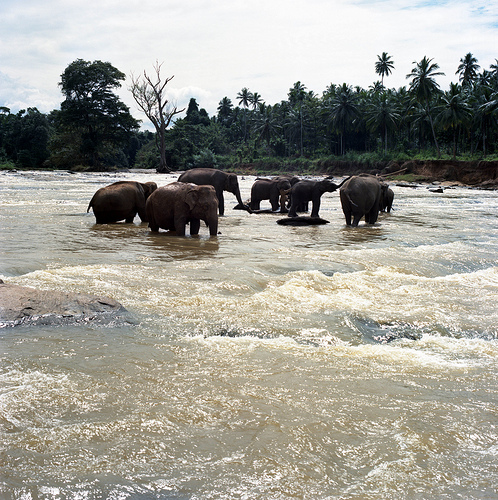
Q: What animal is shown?
A: Elephants.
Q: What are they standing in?
A: River.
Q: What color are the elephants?
A: Grey.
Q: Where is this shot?
A: River.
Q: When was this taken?
A: Daytime.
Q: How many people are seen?
A: 0.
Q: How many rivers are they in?
A: 1.